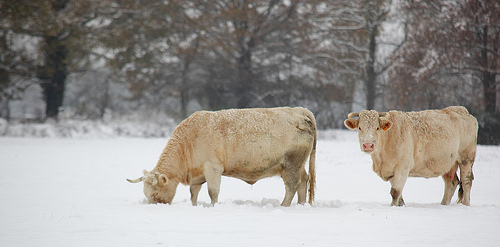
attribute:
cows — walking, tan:
[126, 103, 479, 217]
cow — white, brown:
[134, 105, 321, 211]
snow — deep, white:
[1, 137, 497, 247]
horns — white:
[122, 171, 168, 185]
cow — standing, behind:
[352, 106, 478, 210]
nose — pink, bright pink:
[359, 142, 378, 153]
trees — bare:
[1, 4, 493, 112]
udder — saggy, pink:
[442, 161, 459, 183]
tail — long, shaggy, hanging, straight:
[306, 112, 319, 207]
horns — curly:
[346, 110, 393, 120]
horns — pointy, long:
[125, 176, 147, 186]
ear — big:
[159, 175, 171, 187]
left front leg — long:
[200, 156, 226, 209]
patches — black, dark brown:
[453, 153, 477, 186]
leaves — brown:
[18, 9, 480, 66]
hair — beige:
[169, 121, 288, 163]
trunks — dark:
[37, 51, 66, 118]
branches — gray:
[69, 19, 180, 112]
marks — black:
[235, 157, 308, 183]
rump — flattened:
[282, 103, 320, 156]